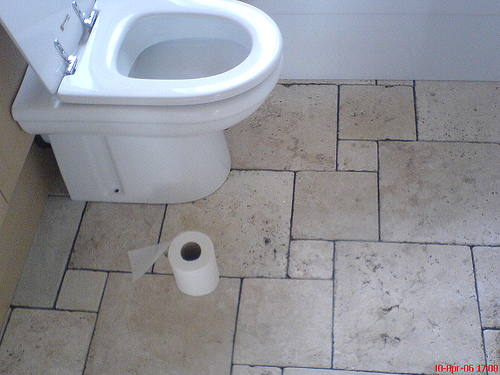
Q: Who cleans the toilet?
A: Maid.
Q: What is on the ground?
A: Toilet paper.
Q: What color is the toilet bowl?
A: White.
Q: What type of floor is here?
A: Stone.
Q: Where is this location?
A: Bathroom.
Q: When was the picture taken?
A: Daytime.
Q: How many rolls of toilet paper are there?
A: One.